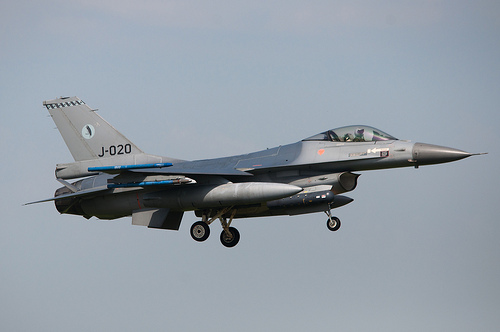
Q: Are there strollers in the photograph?
A: No, there are no strollers.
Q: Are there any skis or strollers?
A: No, there are no strollers or skis.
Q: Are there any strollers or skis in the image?
A: No, there are no strollers or skis.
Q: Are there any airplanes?
A: Yes, there is an airplane.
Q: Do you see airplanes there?
A: Yes, there is an airplane.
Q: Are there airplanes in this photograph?
A: Yes, there is an airplane.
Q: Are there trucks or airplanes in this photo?
A: Yes, there is an airplane.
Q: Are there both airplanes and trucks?
A: No, there is an airplane but no trucks.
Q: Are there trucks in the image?
A: No, there are no trucks.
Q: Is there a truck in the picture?
A: No, there are no trucks.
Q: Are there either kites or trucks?
A: No, there are no trucks or kites.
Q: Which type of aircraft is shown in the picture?
A: The aircraft is an airplane.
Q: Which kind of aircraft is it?
A: The aircraft is an airplane.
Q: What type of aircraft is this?
A: This is an airplane.